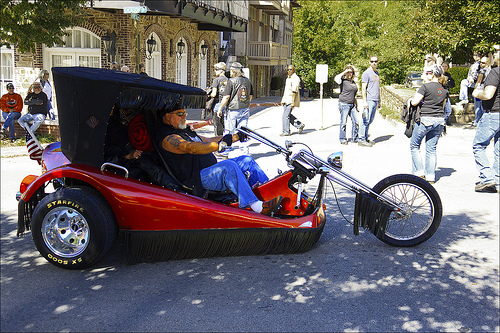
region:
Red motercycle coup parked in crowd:
[25, 63, 438, 263]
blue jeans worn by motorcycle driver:
[200, 153, 275, 205]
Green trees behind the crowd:
[300, 5, 492, 51]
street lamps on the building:
[143, 31, 159, 59]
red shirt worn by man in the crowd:
[0, 88, 20, 115]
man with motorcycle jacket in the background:
[222, 61, 253, 136]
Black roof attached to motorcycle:
[45, 62, 203, 179]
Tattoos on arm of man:
[165, 130, 209, 157]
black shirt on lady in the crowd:
[410, 79, 446, 117]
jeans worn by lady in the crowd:
[407, 119, 443, 178]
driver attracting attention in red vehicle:
[3, 41, 496, 271]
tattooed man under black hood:
[50, 56, 285, 212]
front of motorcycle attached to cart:
[10, 111, 445, 266]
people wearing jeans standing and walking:
[210, 46, 495, 186]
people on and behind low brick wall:
[0, 55, 50, 135]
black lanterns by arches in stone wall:
[130, 5, 220, 105]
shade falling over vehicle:
[5, 60, 485, 325]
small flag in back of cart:
[11, 105, 56, 175]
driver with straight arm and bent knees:
[156, 105, 286, 217]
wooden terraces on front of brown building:
[247, 1, 292, 101]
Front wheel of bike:
[365, 172, 445, 249]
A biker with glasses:
[161, 104, 188, 129]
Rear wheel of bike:
[25, 188, 113, 271]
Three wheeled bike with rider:
[25, 66, 443, 268]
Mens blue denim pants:
[200, 160, 262, 210]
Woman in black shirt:
[402, 61, 449, 183]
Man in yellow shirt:
[281, 63, 306, 136]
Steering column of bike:
[234, 122, 373, 196]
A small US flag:
[21, 120, 53, 162]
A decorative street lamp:
[145, 34, 157, 57]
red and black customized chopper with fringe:
[15, 66, 445, 269]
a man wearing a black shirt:
[154, 102, 284, 217]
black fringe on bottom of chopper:
[113, 221, 325, 263]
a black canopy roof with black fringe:
[51, 65, 207, 169]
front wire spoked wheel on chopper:
[363, 170, 443, 248]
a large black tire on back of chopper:
[29, 188, 116, 270]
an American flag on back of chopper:
[22, 120, 43, 166]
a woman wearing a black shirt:
[401, 64, 448, 185]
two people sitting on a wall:
[0, 81, 52, 143]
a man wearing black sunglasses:
[358, 53, 381, 146]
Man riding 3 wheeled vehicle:
[14, 63, 449, 272]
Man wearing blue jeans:
[198, 155, 273, 209]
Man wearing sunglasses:
[161, 110, 188, 117]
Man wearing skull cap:
[158, 98, 185, 112]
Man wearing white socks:
[246, 197, 267, 214]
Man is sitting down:
[155, 97, 287, 216]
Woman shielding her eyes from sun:
[334, 61, 363, 145]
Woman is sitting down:
[0, 81, 22, 141]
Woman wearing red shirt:
[0, 93, 24, 113]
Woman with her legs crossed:
[1, 80, 26, 145]